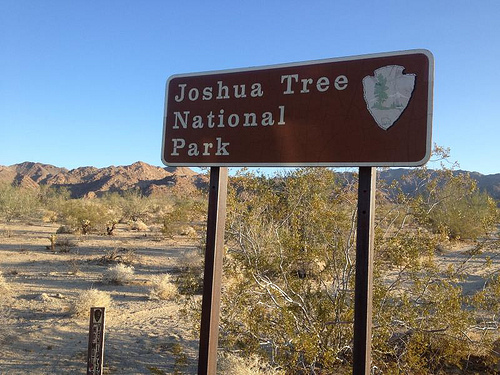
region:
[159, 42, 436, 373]
sign on a metal post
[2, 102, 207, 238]
hills in the background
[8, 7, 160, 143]
patch of clear blue sky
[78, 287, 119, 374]
wooden stake in the ground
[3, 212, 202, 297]
sand on the ground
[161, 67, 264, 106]
the name Joshua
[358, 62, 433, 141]
map of park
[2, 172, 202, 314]
shrubs planted under sand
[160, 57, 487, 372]
green tree behind metal signpost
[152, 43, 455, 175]
rectangular park sign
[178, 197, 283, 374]
brown stand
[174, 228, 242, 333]
brown stand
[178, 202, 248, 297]
brown stand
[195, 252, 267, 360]
brown stand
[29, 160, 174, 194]
the hills are bare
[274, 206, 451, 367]
the bush is dry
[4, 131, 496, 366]
the park is joshua tree national park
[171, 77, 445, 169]
the sign is red in color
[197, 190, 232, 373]
the post is mettalic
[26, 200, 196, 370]
the land is very dry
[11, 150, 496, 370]
no animals are in the photo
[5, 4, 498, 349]
it is hot and dry in the photo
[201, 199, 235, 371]
the metal is brown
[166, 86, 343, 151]
the letters are white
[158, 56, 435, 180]
a brown park sign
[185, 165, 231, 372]
a brown sign post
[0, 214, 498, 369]
the dirt ground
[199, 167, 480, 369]
a tree behind a sign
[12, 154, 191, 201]
a mountain in the distance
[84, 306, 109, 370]
a thermometer in front of a sign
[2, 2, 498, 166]
a clear blue sky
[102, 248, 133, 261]
a short dark stumpy plant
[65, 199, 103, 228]
a tree in the distance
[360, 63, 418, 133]
a white arrow head on a sign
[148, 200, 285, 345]
brown post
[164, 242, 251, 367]
brown post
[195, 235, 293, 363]
brown post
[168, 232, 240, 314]
brown post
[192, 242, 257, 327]
brown post